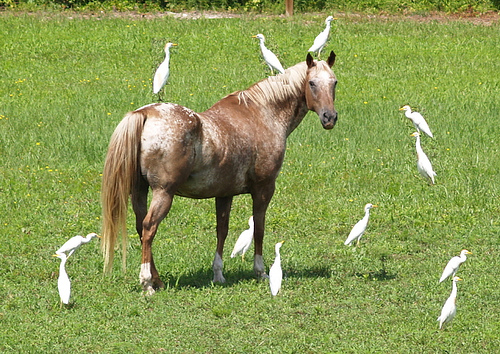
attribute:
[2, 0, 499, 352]
grass — green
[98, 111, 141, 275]
tail — long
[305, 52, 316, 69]
ear — pointy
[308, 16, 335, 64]
bird — white, long, pretty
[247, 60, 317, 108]
mane — blonde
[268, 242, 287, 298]
bird — pretty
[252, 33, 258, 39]
beak — orange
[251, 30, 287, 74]
bird — pretty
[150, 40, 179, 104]
bird — white, pretty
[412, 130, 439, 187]
bird — standing, pretty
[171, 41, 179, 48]
beak — orange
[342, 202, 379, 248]
bird — pretty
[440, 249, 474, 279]
bird — white, pretty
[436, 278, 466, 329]
bird — white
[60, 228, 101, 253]
bird — pretty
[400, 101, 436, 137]
bird — white, pretty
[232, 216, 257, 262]
bird — pretty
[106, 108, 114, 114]
flower — yellow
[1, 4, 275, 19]
path — dirt